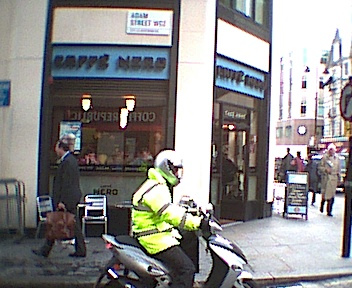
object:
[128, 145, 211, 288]
man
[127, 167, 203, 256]
jacket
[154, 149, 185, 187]
helmet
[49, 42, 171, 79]
sign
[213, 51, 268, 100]
sign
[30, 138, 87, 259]
man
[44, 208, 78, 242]
bag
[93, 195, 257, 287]
motorcycle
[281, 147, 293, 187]
people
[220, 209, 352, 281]
sidewalk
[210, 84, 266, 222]
doorframe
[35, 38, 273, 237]
coffee shop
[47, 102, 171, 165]
windows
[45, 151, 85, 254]
suit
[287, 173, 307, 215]
menu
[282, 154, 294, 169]
jacket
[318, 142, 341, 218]
man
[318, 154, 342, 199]
trench coat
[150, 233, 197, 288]
pants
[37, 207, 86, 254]
pants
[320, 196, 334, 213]
pants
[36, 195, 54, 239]
chair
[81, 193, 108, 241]
chair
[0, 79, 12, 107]
sign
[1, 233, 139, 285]
sidewalk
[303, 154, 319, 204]
man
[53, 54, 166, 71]
name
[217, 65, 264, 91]
name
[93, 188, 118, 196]
name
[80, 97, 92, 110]
light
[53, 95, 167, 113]
ceiling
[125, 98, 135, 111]
light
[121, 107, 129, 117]
light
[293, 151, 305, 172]
person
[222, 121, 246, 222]
door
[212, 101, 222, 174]
window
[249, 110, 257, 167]
window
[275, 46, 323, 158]
building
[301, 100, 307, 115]
window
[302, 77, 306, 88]
window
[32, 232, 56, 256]
leg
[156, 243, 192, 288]
two legs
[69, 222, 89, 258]
two legs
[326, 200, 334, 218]
two legs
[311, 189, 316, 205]
two legs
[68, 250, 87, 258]
shoe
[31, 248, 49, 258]
shoe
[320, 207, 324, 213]
shoe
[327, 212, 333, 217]
shoe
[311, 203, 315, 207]
shoe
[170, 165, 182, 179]
face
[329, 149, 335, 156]
face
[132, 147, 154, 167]
man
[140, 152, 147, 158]
face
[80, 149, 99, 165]
man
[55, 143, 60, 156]
face